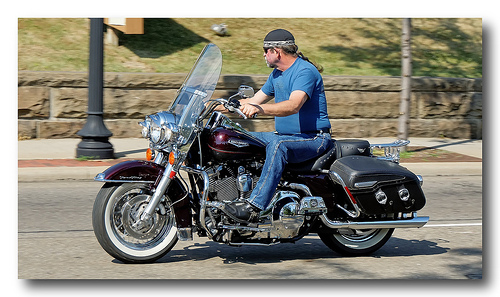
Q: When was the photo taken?
A: Daytime.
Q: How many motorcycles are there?
A: One.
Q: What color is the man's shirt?
A: Blue.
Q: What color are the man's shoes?
A: Black.